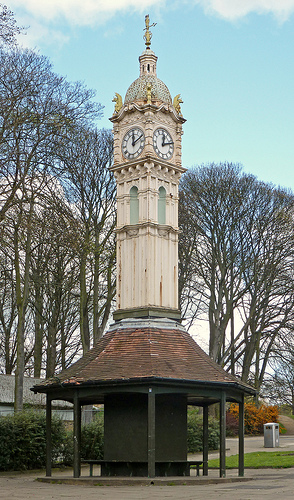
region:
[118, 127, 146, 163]
Black and white clock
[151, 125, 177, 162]
Black and white clock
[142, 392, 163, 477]
Tall Wooden plank on building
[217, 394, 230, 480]
Tall Wooden plank on building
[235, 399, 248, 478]
Tall Wooden plank on building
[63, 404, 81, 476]
Tall Wooden plank on building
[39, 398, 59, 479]
Tall Wooden plank on building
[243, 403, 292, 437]
Bright orange bush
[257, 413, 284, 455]
Silver trashcan on pavement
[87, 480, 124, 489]
Grass growing in the opavement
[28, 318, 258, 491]
an old gazebo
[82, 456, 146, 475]
a bench on the gazebo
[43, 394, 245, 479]
posts supporting the gazebo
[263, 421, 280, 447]
a trash bin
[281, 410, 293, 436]
an empty road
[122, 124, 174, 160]
clocks on the tower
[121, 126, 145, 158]
a clock on one side of the tower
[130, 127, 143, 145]
a long and short hand of the clock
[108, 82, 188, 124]
a decorative structure on top of the tower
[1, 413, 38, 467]
a green bush as fence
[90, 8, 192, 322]
a clock on a tower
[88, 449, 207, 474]
wooden benchs in the building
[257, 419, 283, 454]
a trash can on concrete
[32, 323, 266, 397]
roof over sitting area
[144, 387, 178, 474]
wooden support poles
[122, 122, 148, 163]
clock with white face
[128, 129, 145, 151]
hands on a clock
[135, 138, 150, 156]
roman numbers on a clock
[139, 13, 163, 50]
weather vain on top of tower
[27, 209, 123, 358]
bare trees by tower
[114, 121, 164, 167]
A clock on the tower.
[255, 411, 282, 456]
A garbage bin on the sidealk.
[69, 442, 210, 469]
Benches around the tower.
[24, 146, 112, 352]
Tall tree behind the tower.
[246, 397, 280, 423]
The leaves on the tree is yellow and brown.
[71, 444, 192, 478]
A sitting area attached to the building.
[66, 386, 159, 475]
Poles on the building.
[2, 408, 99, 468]
Bushes next to the house.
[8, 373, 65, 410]
The roof of a house.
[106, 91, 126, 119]
Horses with wings on top of building.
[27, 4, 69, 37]
white clouds in blue sky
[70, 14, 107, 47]
white clouds in blue sky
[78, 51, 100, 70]
white clouds in blue sky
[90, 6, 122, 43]
white clouds in blue sky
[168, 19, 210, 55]
white clouds in blue sky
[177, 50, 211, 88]
white clouds in blue sky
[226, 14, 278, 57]
white clouds in blue sky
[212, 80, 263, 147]
white clouds in blue sky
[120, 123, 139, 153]
clock in tower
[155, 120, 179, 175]
clock in tower